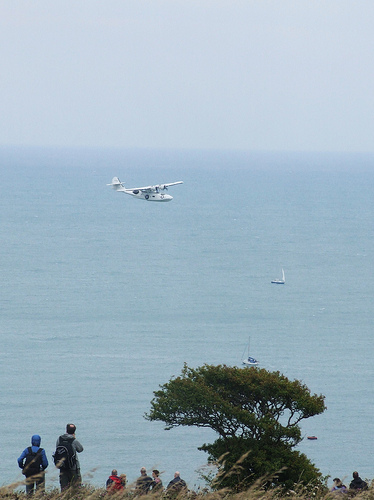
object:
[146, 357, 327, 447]
tree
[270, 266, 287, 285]
sailboat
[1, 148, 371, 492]
water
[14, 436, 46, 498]
person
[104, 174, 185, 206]
plane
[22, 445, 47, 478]
backpack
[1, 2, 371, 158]
sky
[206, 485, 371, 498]
grass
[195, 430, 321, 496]
bush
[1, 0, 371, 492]
air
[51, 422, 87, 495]
person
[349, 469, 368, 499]
person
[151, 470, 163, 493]
person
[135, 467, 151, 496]
person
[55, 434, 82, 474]
gray shirt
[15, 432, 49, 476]
blue shirt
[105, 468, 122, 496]
person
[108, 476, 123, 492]
red shirt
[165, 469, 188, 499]
person